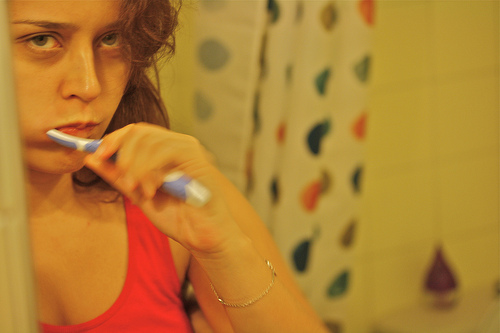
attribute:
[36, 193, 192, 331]
shirt — red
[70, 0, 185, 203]
hair — brown, dark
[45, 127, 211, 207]
toothbrush — white, purple, blue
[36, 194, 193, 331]
top — red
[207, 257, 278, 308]
bracelet — silver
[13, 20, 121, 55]
eyes — GREEN